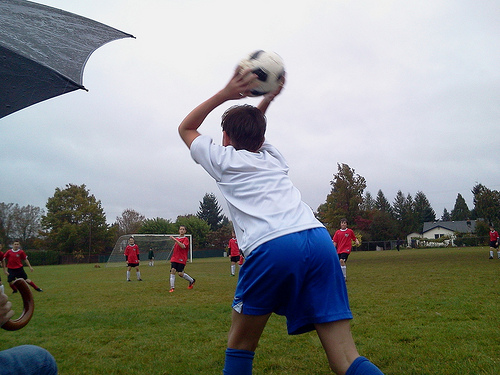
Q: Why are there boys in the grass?
A: Playing soccer.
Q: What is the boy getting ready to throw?
A: Soccer ball.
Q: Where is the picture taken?
A: Soccer field.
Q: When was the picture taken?
A: During a soccer game.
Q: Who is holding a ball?
A: Boy in white shirt.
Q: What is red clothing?
A: Shirts.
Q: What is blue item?
A: Shorts.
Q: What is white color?
A: Shirt.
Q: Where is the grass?
A: On ground.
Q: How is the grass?
A: Short.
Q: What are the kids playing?
A: Baseball.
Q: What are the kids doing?
A: Throwing ball.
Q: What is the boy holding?
A: Ball.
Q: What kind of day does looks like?
A: Rainy.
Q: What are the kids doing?
A: Playing.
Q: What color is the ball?
A: White.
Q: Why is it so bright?
A: Sunlight.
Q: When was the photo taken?
A: The evening.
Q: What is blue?
A: The shorts.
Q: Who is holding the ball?
A: The boy.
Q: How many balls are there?
A: One.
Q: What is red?
A: The shirts.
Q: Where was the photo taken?
A: During a game.